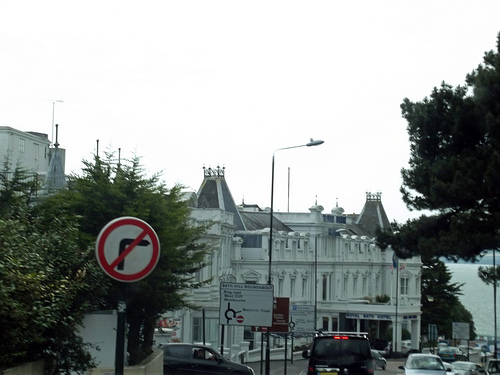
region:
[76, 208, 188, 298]
the sign is red, white, and black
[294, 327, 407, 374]
back of a black van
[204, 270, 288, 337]
a white street sign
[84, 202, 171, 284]
a red circle with a line through it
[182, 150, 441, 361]
this is a white building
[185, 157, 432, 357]
a victorian style building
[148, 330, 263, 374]
this is a black car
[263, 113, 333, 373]
here is a tall streetlight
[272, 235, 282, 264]
arch on the building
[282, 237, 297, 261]
arch on the building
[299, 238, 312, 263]
arch on the building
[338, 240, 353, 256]
arch on the building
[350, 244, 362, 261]
arch on the building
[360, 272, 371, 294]
arch on the building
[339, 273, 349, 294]
arch on the building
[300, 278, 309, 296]
arch on the building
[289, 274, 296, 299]
arch on the building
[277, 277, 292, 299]
arch on the building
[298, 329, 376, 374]
a car on the street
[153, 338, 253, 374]
a car on the street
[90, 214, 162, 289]
a sign warning drivers to not turn right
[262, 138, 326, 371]
a light post on a sidewalk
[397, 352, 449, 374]
a car on the street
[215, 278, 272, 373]
a white sign on a sidewalk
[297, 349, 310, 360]
the side mirror of a car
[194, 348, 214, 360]
a person driving a car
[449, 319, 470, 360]
a white sign on a street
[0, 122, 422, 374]
a line of white buildings on a street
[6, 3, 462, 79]
clear patch of sky with no clouds or sun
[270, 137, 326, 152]
street lamp for lighting the way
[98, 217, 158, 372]
red and white sign on black pole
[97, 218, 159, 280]
no turn sign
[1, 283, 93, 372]
leaves falling over brick fence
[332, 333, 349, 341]
red lights telling those following to slow it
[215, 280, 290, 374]
row of street signs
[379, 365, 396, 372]
paved road for smooth travels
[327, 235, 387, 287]
white building with more than one floor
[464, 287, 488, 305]
body of water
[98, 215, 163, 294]
a round sign on a pole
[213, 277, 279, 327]
a black and white sign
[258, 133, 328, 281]
a light on a pole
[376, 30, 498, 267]
a tree by the street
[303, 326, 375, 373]
a car on a road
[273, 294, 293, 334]
a brown and white sign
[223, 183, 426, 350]
white buildings line the street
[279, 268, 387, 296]
windows on a building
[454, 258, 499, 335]
a crystal clear water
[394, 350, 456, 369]
cars parked on the street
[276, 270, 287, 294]
A window on a building.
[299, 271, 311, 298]
A window on a building.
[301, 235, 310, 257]
A window on a building.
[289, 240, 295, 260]
A window on a building.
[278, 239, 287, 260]
A window on a building.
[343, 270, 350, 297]
A window on a building.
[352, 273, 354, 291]
A window on a building.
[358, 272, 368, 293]
A window on a building.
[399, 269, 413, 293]
A window on a building.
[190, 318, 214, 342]
A window on a building.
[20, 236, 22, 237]
A green leaf on a plant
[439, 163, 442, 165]
A green leaf on a plant